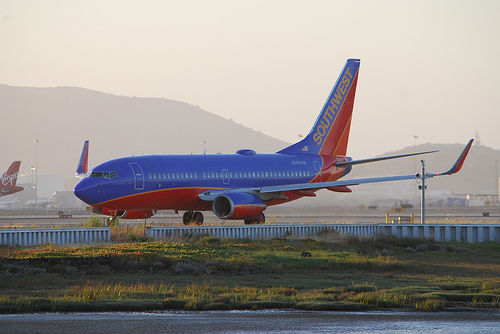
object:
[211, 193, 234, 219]
turbine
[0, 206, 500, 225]
tarmac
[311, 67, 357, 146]
airplane name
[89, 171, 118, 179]
cockpit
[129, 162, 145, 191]
passenger door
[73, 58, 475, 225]
airplane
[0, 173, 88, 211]
wall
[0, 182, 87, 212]
building